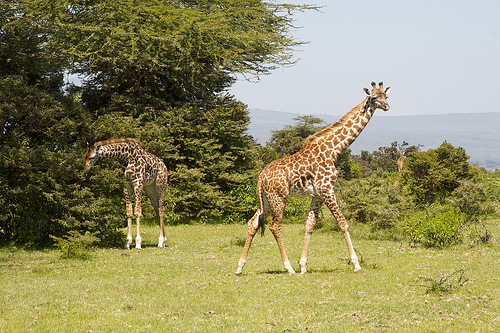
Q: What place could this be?
A: It is a field.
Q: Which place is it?
A: It is a field.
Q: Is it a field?
A: Yes, it is a field.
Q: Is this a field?
A: Yes, it is a field.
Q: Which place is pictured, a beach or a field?
A: It is a field.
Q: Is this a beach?
A: No, it is a field.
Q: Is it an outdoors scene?
A: Yes, it is outdoors.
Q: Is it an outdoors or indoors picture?
A: It is outdoors.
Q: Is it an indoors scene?
A: No, it is outdoors.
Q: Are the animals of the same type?
A: Yes, all the animals are giraffes.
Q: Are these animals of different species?
A: No, all the animals are giraffes.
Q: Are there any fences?
A: No, there are no fences.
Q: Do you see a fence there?
A: No, there are no fences.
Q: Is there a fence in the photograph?
A: No, there are no fences.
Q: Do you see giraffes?
A: Yes, there is a giraffe.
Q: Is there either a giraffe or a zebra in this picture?
A: Yes, there is a giraffe.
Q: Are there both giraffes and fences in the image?
A: No, there is a giraffe but no fences.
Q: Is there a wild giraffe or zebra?
A: Yes, there is a wild giraffe.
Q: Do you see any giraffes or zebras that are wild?
A: Yes, the giraffe is wild.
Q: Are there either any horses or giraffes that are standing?
A: Yes, the giraffe is standing.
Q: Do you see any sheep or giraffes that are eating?
A: Yes, the giraffe is eating.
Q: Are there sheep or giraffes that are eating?
A: Yes, the giraffe is eating.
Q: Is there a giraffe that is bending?
A: Yes, there is a giraffe that is bending.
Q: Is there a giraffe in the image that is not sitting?
A: Yes, there is a giraffe that is bending.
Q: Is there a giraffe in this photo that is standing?
A: Yes, there is a giraffe that is standing.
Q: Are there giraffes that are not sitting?
A: Yes, there is a giraffe that is standing.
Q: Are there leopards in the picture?
A: No, there are no leopards.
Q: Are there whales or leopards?
A: No, there are no leopards or whales.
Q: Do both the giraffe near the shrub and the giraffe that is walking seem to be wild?
A: Yes, both the giraffe and the giraffe are wild.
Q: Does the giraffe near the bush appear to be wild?
A: Yes, the giraffe is wild.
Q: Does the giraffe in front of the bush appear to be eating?
A: Yes, the giraffe is eating.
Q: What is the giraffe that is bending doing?
A: The giraffe is eating.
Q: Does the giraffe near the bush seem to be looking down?
A: No, the giraffe is eating.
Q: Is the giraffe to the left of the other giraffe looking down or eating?
A: The giraffe is eating.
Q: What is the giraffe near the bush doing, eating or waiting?
A: The giraffe is eating.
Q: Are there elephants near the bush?
A: No, there is a giraffe near the bush.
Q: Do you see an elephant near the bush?
A: No, there is a giraffe near the bush.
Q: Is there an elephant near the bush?
A: No, there is a giraffe near the bush.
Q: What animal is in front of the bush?
A: The animal is a giraffe.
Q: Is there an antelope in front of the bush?
A: No, there is a giraffe in front of the bush.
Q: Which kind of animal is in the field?
A: The animal is a giraffe.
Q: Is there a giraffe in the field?
A: Yes, there is a giraffe in the field.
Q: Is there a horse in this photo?
A: No, there are no horses.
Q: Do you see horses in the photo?
A: No, there are no horses.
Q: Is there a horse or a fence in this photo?
A: No, there are no horses or fences.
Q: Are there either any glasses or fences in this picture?
A: No, there are no fences or glasses.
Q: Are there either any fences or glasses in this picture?
A: No, there are no fences or glasses.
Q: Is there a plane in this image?
A: No, there are no airplanes.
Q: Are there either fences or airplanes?
A: No, there are no airplanes or fences.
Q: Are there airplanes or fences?
A: No, there are no airplanes or fences.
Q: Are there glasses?
A: No, there are no glasses.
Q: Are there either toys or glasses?
A: No, there are no glasses or toys.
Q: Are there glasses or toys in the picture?
A: No, there are no glasses or toys.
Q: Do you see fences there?
A: No, there are no fences.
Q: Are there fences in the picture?
A: No, there are no fences.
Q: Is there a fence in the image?
A: No, there are no fences.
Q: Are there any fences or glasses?
A: No, there are no fences or glasses.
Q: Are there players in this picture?
A: No, there are no players.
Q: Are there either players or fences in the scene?
A: No, there are no players or fences.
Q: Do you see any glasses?
A: No, there are no glasses.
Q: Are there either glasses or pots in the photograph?
A: No, there are no glasses or pots.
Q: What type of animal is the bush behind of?
A: The bush is behind the giraffe.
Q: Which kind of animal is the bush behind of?
A: The bush is behind the giraffe.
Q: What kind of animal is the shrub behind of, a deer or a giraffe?
A: The shrub is behind a giraffe.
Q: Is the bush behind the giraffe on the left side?
A: Yes, the bush is behind the giraffe.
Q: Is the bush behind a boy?
A: No, the bush is behind the giraffe.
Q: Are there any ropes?
A: No, there are no ropes.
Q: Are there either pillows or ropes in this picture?
A: No, there are no ropes or pillows.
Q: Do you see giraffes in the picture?
A: Yes, there is a giraffe.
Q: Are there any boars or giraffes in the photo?
A: Yes, there is a giraffe.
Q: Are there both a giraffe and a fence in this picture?
A: No, there is a giraffe but no fences.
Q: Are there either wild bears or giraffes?
A: Yes, there is a wild giraffe.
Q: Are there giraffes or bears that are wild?
A: Yes, the giraffe is wild.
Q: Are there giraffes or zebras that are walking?
A: Yes, the giraffe is walking.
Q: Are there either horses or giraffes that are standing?
A: Yes, the giraffe is standing.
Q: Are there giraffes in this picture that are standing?
A: Yes, there is a giraffe that is standing.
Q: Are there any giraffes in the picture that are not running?
A: Yes, there is a giraffe that is standing.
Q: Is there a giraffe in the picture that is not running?
A: Yes, there is a giraffe that is standing.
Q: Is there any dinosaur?
A: No, there are no dinosaurs.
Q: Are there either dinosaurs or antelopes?
A: No, there are no dinosaurs or antelopes.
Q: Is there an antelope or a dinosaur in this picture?
A: No, there are no dinosaurs or antelopes.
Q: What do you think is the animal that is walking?
A: The animal is a giraffe.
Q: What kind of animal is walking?
A: The animal is a giraffe.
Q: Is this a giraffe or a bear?
A: This is a giraffe.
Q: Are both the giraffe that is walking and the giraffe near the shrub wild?
A: Yes, both the giraffe and the giraffe are wild.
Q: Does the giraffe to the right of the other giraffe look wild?
A: Yes, the giraffe is wild.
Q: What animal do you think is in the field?
A: The giraffe is in the field.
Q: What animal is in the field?
A: The giraffe is in the field.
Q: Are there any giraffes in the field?
A: Yes, there is a giraffe in the field.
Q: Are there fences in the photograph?
A: No, there are no fences.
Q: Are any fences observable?
A: No, there are no fences.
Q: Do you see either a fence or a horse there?
A: No, there are no fences or horses.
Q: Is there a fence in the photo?
A: No, there are no fences.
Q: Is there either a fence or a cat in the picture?
A: No, there are no fences or cats.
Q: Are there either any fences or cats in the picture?
A: No, there are no fences or cats.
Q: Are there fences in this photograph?
A: No, there are no fences.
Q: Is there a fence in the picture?
A: No, there are no fences.